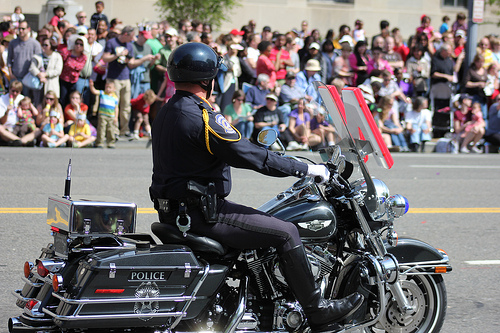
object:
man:
[11, 21, 41, 101]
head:
[17, 21, 29, 40]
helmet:
[166, 40, 221, 87]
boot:
[282, 242, 362, 328]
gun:
[188, 177, 218, 223]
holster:
[195, 178, 224, 223]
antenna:
[58, 158, 78, 201]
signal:
[35, 256, 74, 293]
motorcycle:
[6, 84, 446, 332]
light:
[36, 259, 49, 278]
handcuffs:
[176, 207, 193, 241]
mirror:
[254, 127, 278, 146]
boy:
[69, 112, 96, 148]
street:
[1, 140, 499, 332]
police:
[126, 267, 171, 288]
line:
[3, 195, 500, 219]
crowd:
[0, 3, 500, 152]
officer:
[147, 39, 365, 328]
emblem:
[213, 113, 239, 139]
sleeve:
[194, 105, 311, 179]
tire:
[356, 262, 447, 331]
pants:
[157, 197, 307, 256]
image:
[1, 0, 500, 328]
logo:
[294, 218, 334, 231]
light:
[394, 198, 411, 219]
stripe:
[0, 204, 499, 215]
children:
[85, 81, 121, 148]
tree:
[153, 1, 240, 34]